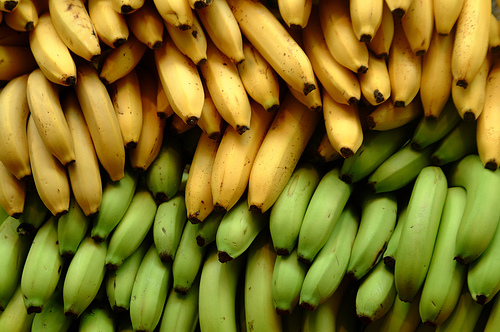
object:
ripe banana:
[24, 68, 77, 168]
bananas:
[343, 153, 499, 332]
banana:
[0, 215, 21, 312]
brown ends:
[339, 146, 355, 159]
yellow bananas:
[0, 0, 499, 226]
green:
[0, 110, 499, 332]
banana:
[229, 1, 318, 97]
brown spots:
[275, 36, 307, 82]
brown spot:
[61, 3, 98, 39]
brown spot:
[191, 30, 198, 39]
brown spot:
[173, 11, 179, 19]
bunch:
[0, 0, 498, 329]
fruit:
[0, 0, 498, 329]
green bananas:
[0, 101, 499, 331]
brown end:
[455, 78, 470, 90]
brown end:
[302, 82, 316, 97]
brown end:
[452, 254, 475, 268]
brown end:
[24, 305, 41, 314]